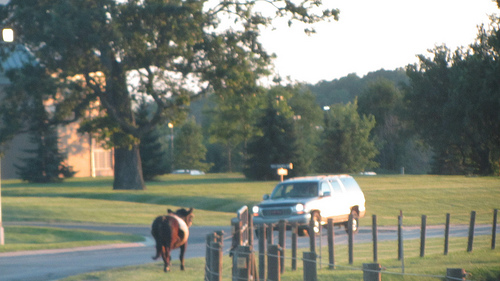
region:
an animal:
[145, 201, 202, 258]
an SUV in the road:
[250, 160, 380, 221]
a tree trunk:
[105, 70, 155, 185]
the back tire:
[346, 210, 361, 230]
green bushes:
[410, 80, 480, 140]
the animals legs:
[151, 248, 176, 268]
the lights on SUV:
[288, 197, 305, 212]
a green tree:
[171, 130, 217, 173]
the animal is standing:
[138, 200, 209, 266]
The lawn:
[377, 171, 471, 204]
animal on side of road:
[152, 202, 194, 276]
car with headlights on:
[246, 174, 375, 234]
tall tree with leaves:
[17, 3, 220, 194]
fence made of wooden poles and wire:
[203, 202, 485, 275]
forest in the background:
[162, 65, 497, 181]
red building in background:
[0, 73, 150, 184]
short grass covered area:
[6, 169, 495, 234]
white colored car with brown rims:
[242, 164, 374, 235]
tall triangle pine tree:
[235, 87, 322, 179]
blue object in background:
[165, 161, 215, 182]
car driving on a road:
[225, 161, 389, 279]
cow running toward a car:
[127, 193, 223, 279]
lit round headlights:
[238, 192, 316, 225]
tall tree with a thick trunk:
[26, 4, 265, 204]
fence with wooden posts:
[186, 187, 470, 279]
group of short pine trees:
[45, 99, 393, 186]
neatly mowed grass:
[64, 142, 437, 240]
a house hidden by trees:
[3, 26, 145, 214]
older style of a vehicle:
[232, 157, 373, 242]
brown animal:
[143, 203, 205, 279]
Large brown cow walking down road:
[146, 204, 190, 279]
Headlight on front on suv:
[292, 203, 307, 215]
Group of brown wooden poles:
[367, 209, 459, 259]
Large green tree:
[88, 10, 163, 190]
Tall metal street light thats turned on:
[166, 117, 178, 175]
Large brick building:
[3, 51, 105, 179]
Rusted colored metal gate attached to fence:
[233, 206, 252, 245]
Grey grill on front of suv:
[261, 206, 295, 216]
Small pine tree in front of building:
[23, 132, 65, 182]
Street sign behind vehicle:
[268, 161, 292, 177]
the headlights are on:
[244, 191, 311, 218]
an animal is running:
[143, 189, 200, 271]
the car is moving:
[232, 171, 366, 231]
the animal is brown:
[135, 193, 197, 268]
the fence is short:
[185, 212, 458, 257]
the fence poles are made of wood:
[220, 212, 457, 254]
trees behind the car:
[221, 87, 388, 177]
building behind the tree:
[6, 64, 129, 177]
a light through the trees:
[2, 15, 39, 62]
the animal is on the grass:
[115, 187, 198, 275]